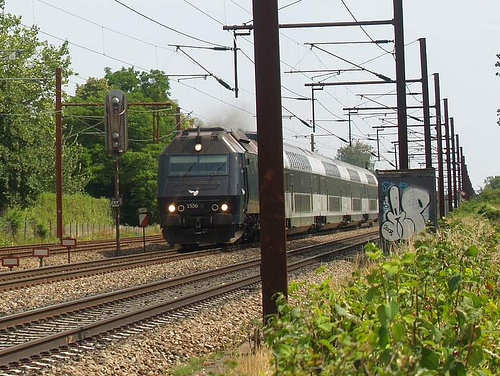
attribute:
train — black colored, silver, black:
[157, 130, 380, 250]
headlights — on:
[166, 143, 227, 212]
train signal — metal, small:
[105, 89, 129, 158]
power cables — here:
[0, 3, 460, 195]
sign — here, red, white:
[137, 212, 147, 227]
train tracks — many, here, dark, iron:
[0, 219, 381, 369]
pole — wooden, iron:
[251, 0, 287, 327]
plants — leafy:
[257, 235, 499, 373]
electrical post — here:
[284, 4, 407, 171]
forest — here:
[1, 2, 201, 230]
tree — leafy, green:
[69, 63, 179, 194]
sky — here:
[3, 2, 499, 194]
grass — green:
[169, 329, 270, 374]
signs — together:
[3, 238, 76, 270]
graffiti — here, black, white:
[381, 168, 439, 260]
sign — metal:
[391, 188, 432, 242]